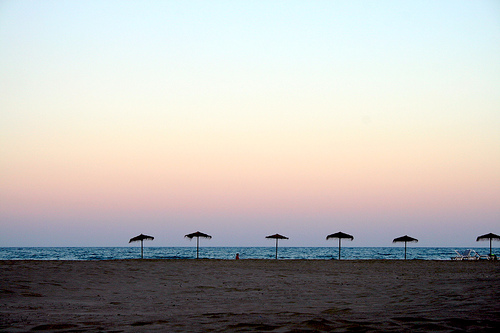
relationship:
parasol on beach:
[129, 233, 154, 259] [0, 261, 496, 329]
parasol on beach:
[129, 233, 154, 259] [300, 275, 374, 297]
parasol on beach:
[265, 233, 289, 259] [24, 257, 499, 326]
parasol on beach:
[184, 231, 212, 259] [4, 255, 499, 320]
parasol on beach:
[265, 233, 289, 259] [4, 255, 499, 320]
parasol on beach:
[326, 232, 354, 261] [4, 255, 499, 320]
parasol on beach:
[392, 234, 418, 260] [4, 255, 499, 320]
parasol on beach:
[476, 233, 500, 260] [4, 255, 499, 320]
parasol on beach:
[392, 234, 418, 260] [0, 261, 496, 329]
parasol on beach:
[326, 232, 354, 261] [0, 261, 496, 329]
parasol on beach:
[265, 233, 289, 259] [0, 261, 496, 329]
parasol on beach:
[184, 231, 212, 259] [0, 261, 496, 329]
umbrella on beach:
[474, 229, 497, 262] [0, 261, 496, 329]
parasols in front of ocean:
[108, 225, 484, 265] [0, 245, 499, 260]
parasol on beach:
[127, 230, 155, 257] [7, 254, 497, 331]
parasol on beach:
[184, 229, 212, 261] [7, 254, 497, 331]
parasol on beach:
[265, 233, 289, 259] [7, 254, 497, 331]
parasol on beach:
[325, 226, 357, 263] [7, 254, 497, 331]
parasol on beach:
[393, 232, 418, 266] [7, 254, 497, 331]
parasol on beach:
[474, 232, 499, 266] [7, 254, 497, 331]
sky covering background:
[0, 0, 499, 244] [27, 24, 486, 196]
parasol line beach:
[392, 234, 418, 260] [7, 248, 499, 320]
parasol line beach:
[326, 232, 354, 261] [7, 248, 499, 320]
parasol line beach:
[265, 233, 289, 259] [7, 248, 499, 320]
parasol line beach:
[129, 233, 154, 259] [7, 248, 499, 320]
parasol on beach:
[184, 231, 212, 259] [5, 17, 499, 322]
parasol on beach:
[392, 234, 418, 260] [7, 254, 497, 331]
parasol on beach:
[326, 232, 354, 261] [7, 254, 497, 331]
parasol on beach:
[262, 231, 294, 265] [7, 254, 497, 331]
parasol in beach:
[129, 233, 154, 259] [0, 259, 500, 333]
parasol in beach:
[184, 231, 212, 259] [0, 259, 500, 333]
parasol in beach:
[265, 233, 289, 259] [0, 259, 500, 333]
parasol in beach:
[326, 232, 354, 261] [0, 259, 500, 333]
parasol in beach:
[392, 234, 418, 260] [0, 259, 500, 333]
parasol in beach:
[476, 233, 500, 260] [0, 259, 500, 333]